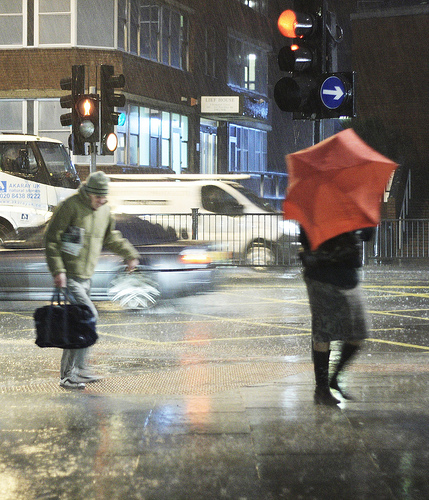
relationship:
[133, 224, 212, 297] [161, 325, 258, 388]
car driving down street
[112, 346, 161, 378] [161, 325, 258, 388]
rain on street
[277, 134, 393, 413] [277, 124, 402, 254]
woman with umbrella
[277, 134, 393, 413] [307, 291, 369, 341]
woman wearing a skirt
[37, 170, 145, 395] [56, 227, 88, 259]
man holding newspaper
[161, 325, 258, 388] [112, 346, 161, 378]
street soaked in rain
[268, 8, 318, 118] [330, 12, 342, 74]
traffic signal on pole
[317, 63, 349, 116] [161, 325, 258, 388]
sign above a street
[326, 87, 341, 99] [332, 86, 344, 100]
arrow pointing right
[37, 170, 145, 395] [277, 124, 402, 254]
man walking with umbrella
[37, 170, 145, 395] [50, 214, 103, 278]
man wearing a jacket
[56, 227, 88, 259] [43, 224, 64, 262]
newspaper under arm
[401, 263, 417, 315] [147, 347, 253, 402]
rain drops falling on ground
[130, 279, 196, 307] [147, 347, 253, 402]
shadow on ground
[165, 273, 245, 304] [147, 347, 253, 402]
light on ground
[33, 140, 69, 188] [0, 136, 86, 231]
window on truck